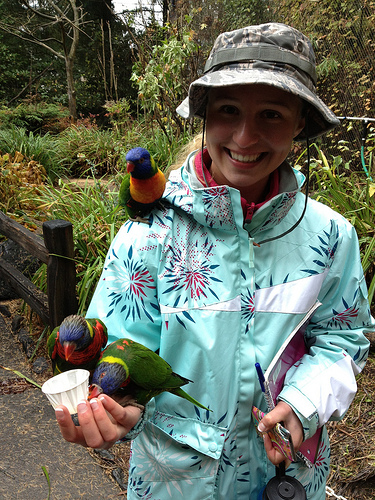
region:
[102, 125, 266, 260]
Parrot on the woman's shoulder.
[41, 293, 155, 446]
Parrots on the woman's hand.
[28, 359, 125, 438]
White container with the parrots.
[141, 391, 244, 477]
Pocket on the jacket.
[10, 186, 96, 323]
Wooden fence in the background.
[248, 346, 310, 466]
Pen with the notebook.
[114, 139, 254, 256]
Blue, yellow and green parrot.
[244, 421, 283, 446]
Nail on the woman.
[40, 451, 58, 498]
Grass on the ground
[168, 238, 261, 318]
Blue and pink design.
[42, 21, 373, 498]
Girl feeding lorikeets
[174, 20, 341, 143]
Green camouflage-patterned hat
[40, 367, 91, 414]
Paper cup for lorikeet food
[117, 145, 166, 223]
Colorful bird on woman's shoulder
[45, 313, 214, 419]
Two rainbow lorikeets sitting on lady's hand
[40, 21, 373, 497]
Smiling blonde girl feeding birds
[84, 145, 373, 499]
Light blue jacket with flower pattern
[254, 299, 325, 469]
Ink pen and composition notebook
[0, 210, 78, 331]
Post and rail fence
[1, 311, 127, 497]
Flat paving stones on ground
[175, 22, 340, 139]
camouflage hat on girl's head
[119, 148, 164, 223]
colorful parrot on girl's shoulder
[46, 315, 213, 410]
two birds sitting on girl's hand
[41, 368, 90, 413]
small paper cup in girl's hand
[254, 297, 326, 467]
book and pen in girl's arm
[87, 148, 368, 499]
blue and pink trench coat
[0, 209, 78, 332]
small wooden fence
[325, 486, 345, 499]
part of white chain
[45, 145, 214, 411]
three birds sitting on girl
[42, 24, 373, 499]
girl holding birds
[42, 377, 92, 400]
a small cup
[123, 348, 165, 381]
green feathers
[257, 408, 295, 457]
women is holding a bird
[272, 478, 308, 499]
top of a water bottle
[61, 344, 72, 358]
a red beak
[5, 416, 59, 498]
the ground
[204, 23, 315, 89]
women is wearing a hat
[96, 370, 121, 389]
bird has a blue head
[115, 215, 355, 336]
a blue jacket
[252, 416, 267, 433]
a fingernail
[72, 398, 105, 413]
fingernails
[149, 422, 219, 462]
pocket on jacket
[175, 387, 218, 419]
the birds tail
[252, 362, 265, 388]
a pen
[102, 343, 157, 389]
a green and blue bird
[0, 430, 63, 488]
the ground is grey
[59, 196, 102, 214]
green plants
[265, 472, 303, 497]
a black lid